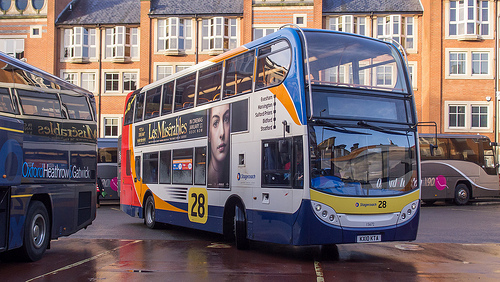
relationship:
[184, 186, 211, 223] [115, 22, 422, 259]
number in bus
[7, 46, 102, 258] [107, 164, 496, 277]
bus in parking lot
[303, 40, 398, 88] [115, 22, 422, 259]
window on bus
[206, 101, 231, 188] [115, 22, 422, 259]
picture on a side of a bus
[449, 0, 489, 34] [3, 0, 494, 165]
window on building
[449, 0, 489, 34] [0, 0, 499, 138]
window on building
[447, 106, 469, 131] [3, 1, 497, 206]
window on building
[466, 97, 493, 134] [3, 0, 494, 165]
window on building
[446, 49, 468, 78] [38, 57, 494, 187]
window on building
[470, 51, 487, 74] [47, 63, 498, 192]
glass window on building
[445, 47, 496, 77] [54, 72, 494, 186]
windows on building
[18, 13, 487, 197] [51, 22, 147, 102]
building with windows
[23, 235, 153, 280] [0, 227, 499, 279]
line painted on pavement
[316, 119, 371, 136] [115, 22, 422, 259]
windshield wipers on bus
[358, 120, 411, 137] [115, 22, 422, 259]
windshield wipers on bus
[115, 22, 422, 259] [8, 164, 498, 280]
bus turning on street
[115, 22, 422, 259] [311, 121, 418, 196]
bus has a windshield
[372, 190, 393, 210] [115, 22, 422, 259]
number on front of bus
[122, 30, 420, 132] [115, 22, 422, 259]
upper deck on bus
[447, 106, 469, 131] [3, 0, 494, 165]
window on building